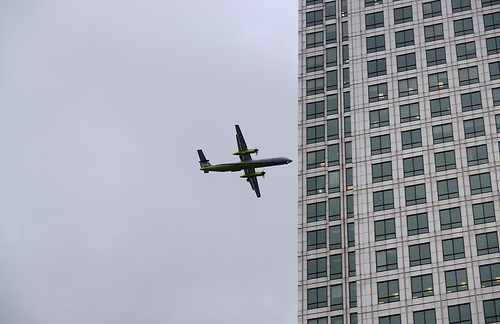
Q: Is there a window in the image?
A: Yes, there is a window.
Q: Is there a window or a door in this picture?
A: Yes, there is a window.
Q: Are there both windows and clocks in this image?
A: No, there is a window but no clocks.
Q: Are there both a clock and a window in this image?
A: No, there is a window but no clocks.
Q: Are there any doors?
A: No, there are no doors.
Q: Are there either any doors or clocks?
A: No, there are no doors or clocks.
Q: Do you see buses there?
A: No, there are no buses.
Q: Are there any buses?
A: No, there are no buses.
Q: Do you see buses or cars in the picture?
A: No, there are no buses or cars.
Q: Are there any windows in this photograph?
A: Yes, there is a window.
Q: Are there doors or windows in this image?
A: Yes, there is a window.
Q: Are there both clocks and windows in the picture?
A: No, there is a window but no clocks.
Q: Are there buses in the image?
A: No, there are no buses.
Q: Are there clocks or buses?
A: No, there are no buses or clocks.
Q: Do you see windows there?
A: Yes, there is a window.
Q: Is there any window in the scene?
A: Yes, there is a window.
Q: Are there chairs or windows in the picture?
A: Yes, there is a window.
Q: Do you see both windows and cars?
A: No, there is a window but no cars.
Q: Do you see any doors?
A: No, there are no doors.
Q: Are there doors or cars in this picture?
A: No, there are no doors or cars.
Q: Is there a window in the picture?
A: Yes, there is a window.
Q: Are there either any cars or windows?
A: Yes, there is a window.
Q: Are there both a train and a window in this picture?
A: No, there is a window but no trains.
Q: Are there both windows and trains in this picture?
A: No, there is a window but no trains.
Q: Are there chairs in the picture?
A: No, there are no chairs.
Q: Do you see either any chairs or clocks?
A: No, there are no chairs or clocks.